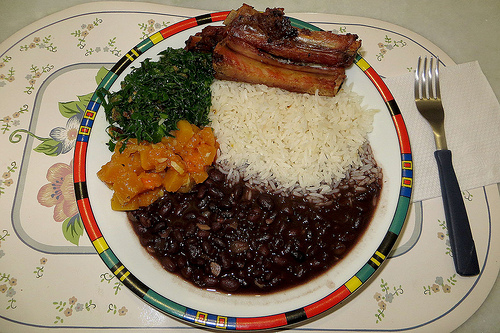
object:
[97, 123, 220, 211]
carrots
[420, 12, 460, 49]
table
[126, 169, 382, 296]
beans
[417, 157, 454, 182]
ground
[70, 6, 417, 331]
plate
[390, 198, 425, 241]
ground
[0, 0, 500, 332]
food tray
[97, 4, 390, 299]
food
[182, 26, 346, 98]
meat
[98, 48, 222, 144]
greens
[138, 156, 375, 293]
stew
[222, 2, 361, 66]
fried meat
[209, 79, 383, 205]
rice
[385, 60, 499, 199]
napkin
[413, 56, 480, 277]
fork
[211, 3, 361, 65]
ribs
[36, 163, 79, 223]
flower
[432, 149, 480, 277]
handle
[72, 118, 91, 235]
edge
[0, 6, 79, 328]
place mat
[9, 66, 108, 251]
design